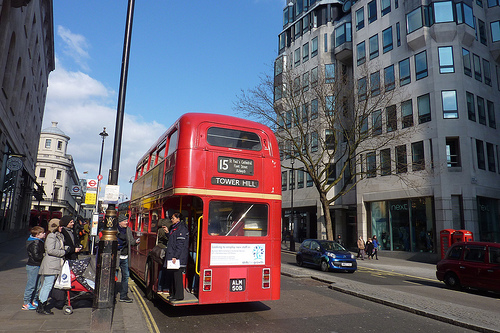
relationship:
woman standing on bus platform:
[164, 214, 186, 299] [177, 291, 200, 303]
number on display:
[217, 156, 228, 169] [217, 153, 255, 176]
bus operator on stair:
[163, 208, 187, 302] [151, 286, 199, 307]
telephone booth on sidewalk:
[439, 228, 456, 260] [282, 238, 445, 283]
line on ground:
[122, 272, 160, 330] [126, 270, 497, 330]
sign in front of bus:
[210, 240, 266, 264] [128, 111, 280, 305]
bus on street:
[128, 111, 280, 305] [126, 270, 497, 330]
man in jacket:
[164, 210, 190, 300] [164, 221, 188, 266]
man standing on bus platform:
[164, 210, 190, 300] [158, 290, 200, 304]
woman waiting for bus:
[35, 218, 74, 316] [128, 111, 280, 305]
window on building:
[442, 88, 460, 118] [270, 0, 496, 259]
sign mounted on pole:
[84, 176, 99, 189] [89, 174, 101, 255]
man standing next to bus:
[115, 212, 141, 304] [128, 111, 280, 305]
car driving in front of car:
[434, 238, 484, 292] [292, 235, 359, 273]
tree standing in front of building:
[228, 45, 447, 248] [270, 0, 496, 259]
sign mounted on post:
[101, 181, 120, 206] [88, 1, 138, 331]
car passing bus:
[296, 235, 364, 285] [124, 107, 294, 322]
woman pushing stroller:
[58, 210, 80, 304] [58, 256, 104, 321]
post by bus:
[99, 14, 128, 328] [131, 105, 305, 319]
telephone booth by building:
[433, 231, 477, 292] [348, 3, 483, 256]